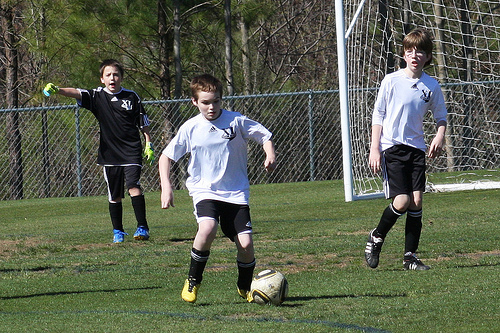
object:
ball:
[246, 269, 290, 307]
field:
[0, 170, 500, 333]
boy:
[157, 74, 277, 304]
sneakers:
[402, 251, 431, 271]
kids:
[360, 29, 449, 270]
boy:
[364, 31, 450, 271]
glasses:
[400, 48, 431, 55]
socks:
[189, 248, 211, 284]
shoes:
[112, 229, 125, 243]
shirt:
[160, 109, 273, 206]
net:
[339, 0, 497, 195]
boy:
[43, 58, 155, 244]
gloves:
[42, 82, 60, 98]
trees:
[101, 0, 212, 192]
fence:
[0, 81, 500, 202]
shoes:
[181, 278, 202, 303]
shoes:
[362, 228, 385, 269]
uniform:
[74, 88, 150, 200]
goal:
[333, 0, 500, 201]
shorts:
[102, 163, 143, 201]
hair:
[188, 74, 223, 104]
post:
[334, 0, 352, 200]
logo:
[221, 126, 237, 142]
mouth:
[411, 61, 419, 67]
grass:
[0, 171, 500, 331]